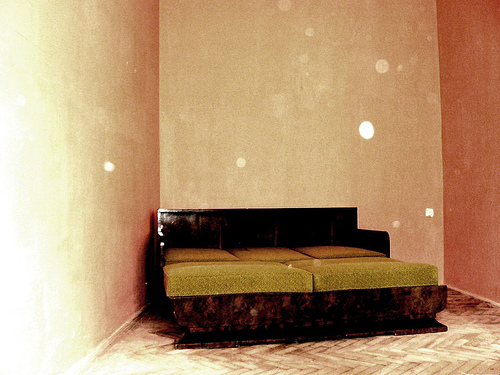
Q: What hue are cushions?
A: Green.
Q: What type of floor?
A: Wooden.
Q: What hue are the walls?
A: Brown.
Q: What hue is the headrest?
A: Brown.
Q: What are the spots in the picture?
A: Light glare.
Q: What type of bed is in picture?
A: Sofa bed.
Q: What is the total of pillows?
A: Five.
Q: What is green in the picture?
A: The pillow.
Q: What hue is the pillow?
A: Green.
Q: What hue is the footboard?
A: Brown.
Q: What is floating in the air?
A: White orbs.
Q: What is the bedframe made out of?
A: Wood.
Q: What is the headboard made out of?
A: Wood.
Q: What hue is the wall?
A: Pink.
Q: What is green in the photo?
A: The pillow.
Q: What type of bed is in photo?
A: Pull out.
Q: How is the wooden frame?
A: Clean.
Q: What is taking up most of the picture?
A: A bed.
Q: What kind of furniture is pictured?
A: A bed.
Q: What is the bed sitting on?
A: A floor.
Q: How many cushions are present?
A: Five.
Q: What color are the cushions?
A: Green.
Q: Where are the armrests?
A: On the sides.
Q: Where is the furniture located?
A: Left corner.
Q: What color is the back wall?
A: Tan.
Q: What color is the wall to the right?
A: Red.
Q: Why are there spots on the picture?
A: Dirty camera lens.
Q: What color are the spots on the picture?
A: White.